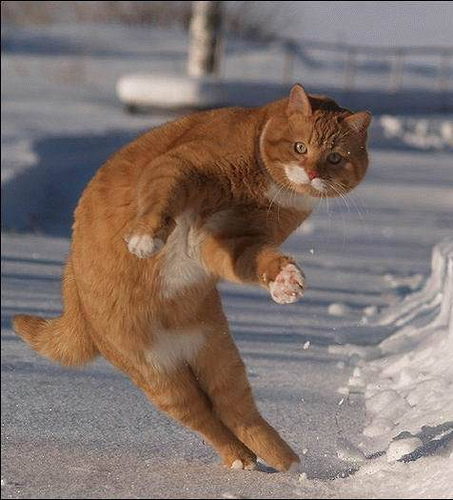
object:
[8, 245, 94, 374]
tail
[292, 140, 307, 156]
eye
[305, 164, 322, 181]
nose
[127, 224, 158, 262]
paw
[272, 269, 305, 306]
claw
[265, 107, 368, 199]
facial expression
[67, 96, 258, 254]
back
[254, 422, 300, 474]
feet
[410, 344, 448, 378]
snow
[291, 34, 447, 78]
bridge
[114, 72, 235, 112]
object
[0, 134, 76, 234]
shadow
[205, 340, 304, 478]
leg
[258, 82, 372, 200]
head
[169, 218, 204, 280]
patch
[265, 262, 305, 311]
paws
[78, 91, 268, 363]
body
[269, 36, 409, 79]
fence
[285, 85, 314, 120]
ear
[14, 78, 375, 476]
cat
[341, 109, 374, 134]
ear